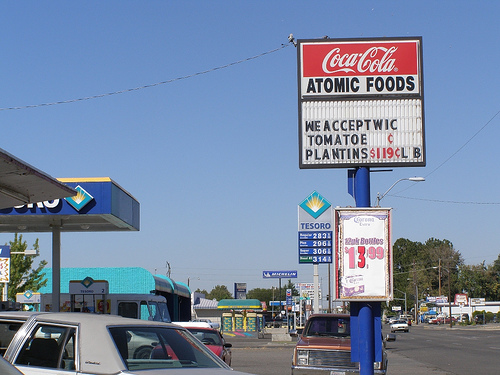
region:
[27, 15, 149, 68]
the sky is blue and clear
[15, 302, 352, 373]
the cars at the gas station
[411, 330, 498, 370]
the street is paved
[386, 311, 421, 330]
the car in the street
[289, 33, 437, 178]
the coca cola sign on the pole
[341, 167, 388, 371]
the pole is blue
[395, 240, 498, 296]
the trees with green leaves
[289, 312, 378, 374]
the brown car at the gas station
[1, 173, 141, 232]
the blue awning at the gas station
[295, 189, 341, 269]
the prices at the gas station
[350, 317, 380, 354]
blue post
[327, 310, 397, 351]
blue post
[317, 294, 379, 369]
blue post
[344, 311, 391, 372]
blue post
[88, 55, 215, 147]
cable wire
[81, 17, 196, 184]
cable wire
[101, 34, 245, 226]
cable wire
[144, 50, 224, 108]
cable wire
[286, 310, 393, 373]
A brown car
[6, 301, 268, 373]
A silver car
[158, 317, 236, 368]
A red car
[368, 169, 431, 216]
A street light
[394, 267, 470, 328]
A line of street lights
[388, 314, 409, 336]
A white sedan on the road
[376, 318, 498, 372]
an asphalt road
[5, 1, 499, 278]
A clear blue sky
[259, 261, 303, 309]
A tall michelin sign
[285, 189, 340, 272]
A tesoro gas station price sign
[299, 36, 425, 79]
white logo on red rectangle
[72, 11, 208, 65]
blue of daytime sky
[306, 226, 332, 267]
rows of numbers on sign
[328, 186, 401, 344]
sign on blue pole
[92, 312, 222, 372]
back window of car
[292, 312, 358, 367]
front of brown truck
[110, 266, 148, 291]
side of green building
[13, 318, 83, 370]
back window of car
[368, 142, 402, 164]
red numbers on sign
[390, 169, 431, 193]
street light on curved pole